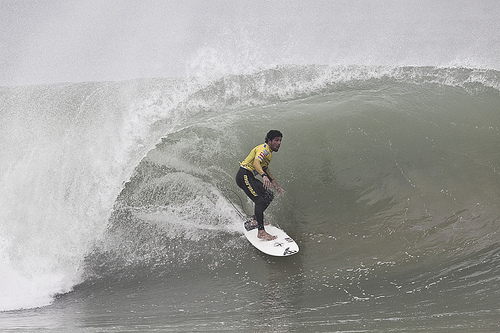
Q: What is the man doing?
A: Surfing.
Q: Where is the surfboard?
A: In the water.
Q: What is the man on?
A: A surfboard.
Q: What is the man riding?
A: A wave.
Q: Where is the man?
A: Ocean.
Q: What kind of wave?
A: A rolling.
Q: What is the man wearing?
A: Wetsuit.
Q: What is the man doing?
A: Surfing.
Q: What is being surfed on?
A: A wave.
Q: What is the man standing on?
A: A surfboard.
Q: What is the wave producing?
A: Foam.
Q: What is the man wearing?
A: A wet suit.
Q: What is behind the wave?
A: A cloudy sky.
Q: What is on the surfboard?
A: A surfer.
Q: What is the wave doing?
A: Crashing down.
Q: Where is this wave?
A: In the ocean.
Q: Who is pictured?
A: A man.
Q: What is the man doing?
A: Surfing.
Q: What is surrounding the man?
A: A wave.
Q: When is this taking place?
A: Daytime.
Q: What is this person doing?
A: Surfing.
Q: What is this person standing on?
A: Surfboard.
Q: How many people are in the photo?
A: One.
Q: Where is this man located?
A: Ocean.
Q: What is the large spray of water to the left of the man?
A: Wave.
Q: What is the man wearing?
A: Wetsuit.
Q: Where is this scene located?
A: In the ocean.